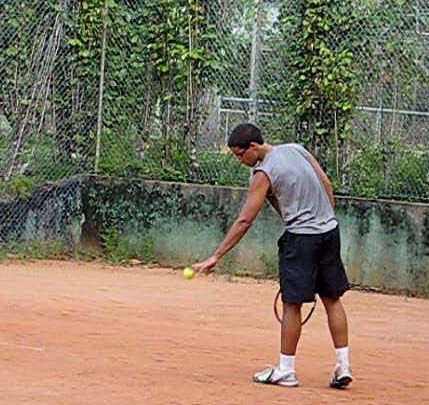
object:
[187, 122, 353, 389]
man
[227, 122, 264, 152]
hair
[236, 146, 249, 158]
glasses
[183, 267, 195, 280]
tennis ball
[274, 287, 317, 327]
tennis racquet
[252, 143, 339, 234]
pullover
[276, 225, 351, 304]
shorts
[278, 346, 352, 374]
socks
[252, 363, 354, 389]
tennis shoes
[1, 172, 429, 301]
wall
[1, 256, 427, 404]
tennis court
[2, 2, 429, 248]
fence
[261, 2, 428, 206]
trees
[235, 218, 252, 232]
elbow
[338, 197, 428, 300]
algae